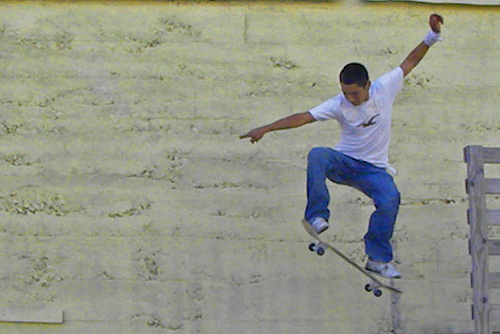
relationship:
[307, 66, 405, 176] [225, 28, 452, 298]
shirt on skateboarder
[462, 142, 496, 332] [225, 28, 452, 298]
pallet right of skateboarder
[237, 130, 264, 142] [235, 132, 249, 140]
hand pointing finger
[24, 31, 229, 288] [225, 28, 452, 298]
white wall behind skateboarder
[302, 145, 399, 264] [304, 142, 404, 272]
jeans has legs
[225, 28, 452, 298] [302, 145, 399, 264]
skateboarder wearing jeans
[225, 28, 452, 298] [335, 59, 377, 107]
skateboarder has head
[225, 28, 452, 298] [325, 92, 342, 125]
skateboarder has shoulder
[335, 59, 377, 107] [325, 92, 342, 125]
head on shoulder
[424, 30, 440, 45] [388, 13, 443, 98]
sweatband on left arm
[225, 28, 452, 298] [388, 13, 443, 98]
skateboarder has left arm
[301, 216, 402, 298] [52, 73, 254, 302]
skateboarder in front of wall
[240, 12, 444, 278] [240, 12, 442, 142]
guy with arms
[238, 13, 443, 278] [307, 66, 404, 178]
boy wearing t-shirt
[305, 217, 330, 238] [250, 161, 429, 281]
shoe on foot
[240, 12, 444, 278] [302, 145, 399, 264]
guy wearing jeans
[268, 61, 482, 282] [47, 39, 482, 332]
man jumping in air